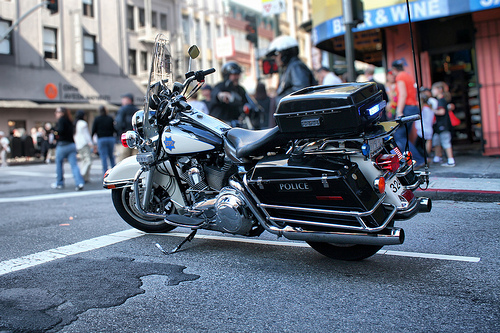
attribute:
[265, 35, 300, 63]
helmet — white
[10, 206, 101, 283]
stripe — white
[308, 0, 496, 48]
sign — store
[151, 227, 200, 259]
kickstand — down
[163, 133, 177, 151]
emblem — police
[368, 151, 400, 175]
light — rear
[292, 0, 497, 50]
sign — store